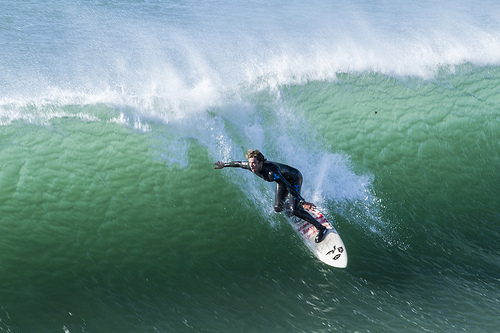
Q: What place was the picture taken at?
A: It was taken at the ocean.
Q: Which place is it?
A: It is an ocean.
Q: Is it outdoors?
A: Yes, it is outdoors.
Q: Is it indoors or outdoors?
A: It is outdoors.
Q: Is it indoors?
A: No, it is outdoors.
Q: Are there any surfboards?
A: Yes, there is a surfboard.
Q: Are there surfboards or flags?
A: Yes, there is a surfboard.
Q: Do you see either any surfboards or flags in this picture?
A: Yes, there is a surfboard.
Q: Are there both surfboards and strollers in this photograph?
A: No, there is a surfboard but no strollers.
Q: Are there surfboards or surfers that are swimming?
A: Yes, the surfboard is swimming.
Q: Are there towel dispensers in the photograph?
A: No, there are no towel dispensers.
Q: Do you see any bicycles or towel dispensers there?
A: No, there are no towel dispensers or bicycles.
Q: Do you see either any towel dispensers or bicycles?
A: No, there are no towel dispensers or bicycles.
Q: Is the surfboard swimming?
A: Yes, the surfboard is swimming.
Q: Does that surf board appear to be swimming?
A: Yes, the surf board is swimming.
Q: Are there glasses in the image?
A: No, there are no glasses.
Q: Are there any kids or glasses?
A: No, there are no glasses or kids.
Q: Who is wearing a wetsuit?
A: The man is wearing a wetsuit.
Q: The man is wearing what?
A: The man is wearing a wet suit.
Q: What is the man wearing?
A: The man is wearing a wet suit.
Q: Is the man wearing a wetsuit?
A: Yes, the man is wearing a wetsuit.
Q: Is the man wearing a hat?
A: No, the man is wearing a wetsuit.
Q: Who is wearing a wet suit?
A: The man is wearing a wet suit.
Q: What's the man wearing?
A: The man is wearing a wet suit.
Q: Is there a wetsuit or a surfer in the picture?
A: Yes, there is a wetsuit.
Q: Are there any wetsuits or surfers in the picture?
A: Yes, there is a wetsuit.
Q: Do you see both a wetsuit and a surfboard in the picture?
A: Yes, there are both a wetsuit and a surfboard.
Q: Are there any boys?
A: No, there are no boys.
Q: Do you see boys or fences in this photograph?
A: No, there are no boys or fences.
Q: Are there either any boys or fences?
A: No, there are no boys or fences.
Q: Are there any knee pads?
A: No, there are no knee pads.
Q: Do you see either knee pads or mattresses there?
A: No, there are no knee pads or mattresses.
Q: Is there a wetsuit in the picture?
A: Yes, there is a wetsuit.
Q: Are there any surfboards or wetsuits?
A: Yes, there is a wetsuit.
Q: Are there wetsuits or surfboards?
A: Yes, there is a wetsuit.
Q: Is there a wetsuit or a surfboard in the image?
A: Yes, there is a wetsuit.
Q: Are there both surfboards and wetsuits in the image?
A: Yes, there are both a wetsuit and a surfboard.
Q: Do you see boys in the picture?
A: No, there are no boys.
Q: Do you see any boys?
A: No, there are no boys.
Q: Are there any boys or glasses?
A: No, there are no boys or glasses.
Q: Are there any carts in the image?
A: No, there are no carts.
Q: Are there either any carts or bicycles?
A: No, there are no carts or bicycles.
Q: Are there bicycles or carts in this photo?
A: No, there are no carts or bicycles.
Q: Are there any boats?
A: No, there are no boats.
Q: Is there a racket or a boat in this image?
A: No, there are no boats or rackets.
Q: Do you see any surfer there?
A: Yes, there is a surfer.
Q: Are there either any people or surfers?
A: Yes, there is a surfer.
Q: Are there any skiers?
A: No, there are no skiers.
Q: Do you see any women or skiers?
A: No, there are no skiers or women.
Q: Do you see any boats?
A: No, there are no boats.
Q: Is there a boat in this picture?
A: No, there are no boats.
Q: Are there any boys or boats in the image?
A: No, there are no boats or boys.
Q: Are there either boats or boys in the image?
A: No, there are no boats or boys.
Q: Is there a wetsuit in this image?
A: Yes, there is a wetsuit.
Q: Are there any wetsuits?
A: Yes, there is a wetsuit.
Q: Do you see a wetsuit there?
A: Yes, there is a wetsuit.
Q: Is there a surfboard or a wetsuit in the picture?
A: Yes, there is a wetsuit.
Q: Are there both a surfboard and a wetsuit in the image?
A: Yes, there are both a wetsuit and a surfboard.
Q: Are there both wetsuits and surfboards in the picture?
A: Yes, there are both a wetsuit and a surfboard.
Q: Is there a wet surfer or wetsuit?
A: Yes, there is a wet wetsuit.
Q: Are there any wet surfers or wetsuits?
A: Yes, there is a wet wetsuit.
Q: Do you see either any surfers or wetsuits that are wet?
A: Yes, the wetsuit is wet.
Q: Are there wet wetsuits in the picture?
A: Yes, there is a wet wetsuit.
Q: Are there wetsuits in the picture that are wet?
A: Yes, there is a wetsuit that is wet.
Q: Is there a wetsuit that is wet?
A: Yes, there is a wetsuit that is wet.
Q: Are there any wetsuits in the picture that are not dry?
A: Yes, there is a wet wetsuit.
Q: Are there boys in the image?
A: No, there are no boys.